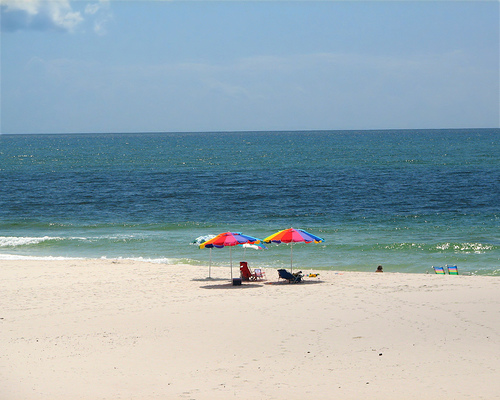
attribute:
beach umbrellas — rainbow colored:
[198, 220, 326, 256]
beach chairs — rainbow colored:
[432, 263, 462, 280]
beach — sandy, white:
[4, 247, 497, 398]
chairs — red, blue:
[229, 261, 316, 290]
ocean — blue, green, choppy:
[3, 129, 496, 276]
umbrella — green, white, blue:
[188, 233, 217, 245]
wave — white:
[2, 230, 109, 250]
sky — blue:
[3, 8, 497, 130]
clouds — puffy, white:
[1, 3, 121, 47]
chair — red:
[235, 261, 261, 284]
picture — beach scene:
[5, 5, 496, 396]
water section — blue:
[9, 157, 496, 227]